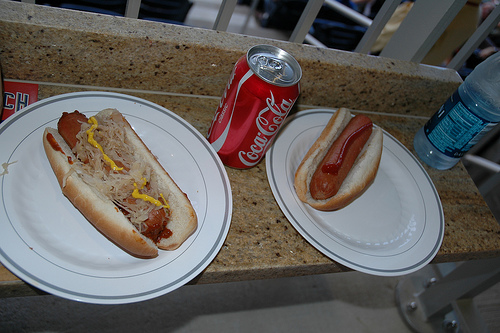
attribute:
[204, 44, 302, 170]
can — coca cola, closed, soda, red, unopened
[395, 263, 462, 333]
base — round, metal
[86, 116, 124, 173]
mustard — yellow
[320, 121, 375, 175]
ketchup — red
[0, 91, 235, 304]
plate — white, plain white, round, gray trimmed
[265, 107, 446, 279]
plate — white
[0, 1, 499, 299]
counter — tan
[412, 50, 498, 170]
bottle — water, clear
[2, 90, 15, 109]
c — blue, white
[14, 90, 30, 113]
h — blue, white